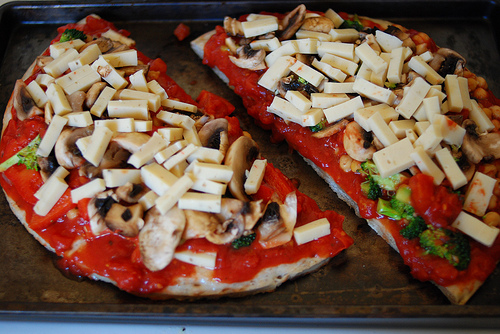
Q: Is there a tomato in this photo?
A: Yes, there is a tomato.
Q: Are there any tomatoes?
A: Yes, there is a tomato.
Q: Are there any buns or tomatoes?
A: Yes, there is a tomato.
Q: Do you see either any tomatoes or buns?
A: Yes, there is a tomato.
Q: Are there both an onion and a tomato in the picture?
A: No, there is a tomato but no onions.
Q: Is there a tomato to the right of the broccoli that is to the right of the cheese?
A: Yes, there is a tomato to the right of the broccoli.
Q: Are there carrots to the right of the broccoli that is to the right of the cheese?
A: No, there is a tomato to the right of the broccoli.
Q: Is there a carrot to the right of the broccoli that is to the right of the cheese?
A: No, there is a tomato to the right of the broccoli.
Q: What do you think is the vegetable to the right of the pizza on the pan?
A: The vegetable is a tomato.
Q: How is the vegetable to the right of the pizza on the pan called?
A: The vegetable is a tomato.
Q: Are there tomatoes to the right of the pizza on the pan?
A: Yes, there is a tomato to the right of the pizza.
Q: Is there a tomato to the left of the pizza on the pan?
A: No, the tomato is to the right of the pizza.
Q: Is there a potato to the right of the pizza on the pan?
A: No, there is a tomato to the right of the pizza.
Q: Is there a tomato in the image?
A: Yes, there is a tomato.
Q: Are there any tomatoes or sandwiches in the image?
A: Yes, there is a tomato.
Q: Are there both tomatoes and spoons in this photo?
A: No, there is a tomato but no spoons.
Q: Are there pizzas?
A: Yes, there is a pizza.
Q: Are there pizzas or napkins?
A: Yes, there is a pizza.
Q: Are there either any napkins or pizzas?
A: Yes, there is a pizza.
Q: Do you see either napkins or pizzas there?
A: Yes, there is a pizza.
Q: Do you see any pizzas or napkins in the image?
A: Yes, there is a pizza.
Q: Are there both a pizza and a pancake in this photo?
A: No, there is a pizza but no pancakes.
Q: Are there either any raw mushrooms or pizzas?
A: Yes, there is a raw pizza.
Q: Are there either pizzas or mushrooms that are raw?
A: Yes, the pizza is raw.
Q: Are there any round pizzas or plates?
A: Yes, there is a round pizza.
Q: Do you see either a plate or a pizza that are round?
A: Yes, the pizza is round.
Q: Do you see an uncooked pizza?
A: Yes, there is an uncooked pizza.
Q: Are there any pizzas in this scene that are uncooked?
A: Yes, there is a pizza that is uncooked.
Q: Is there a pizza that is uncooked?
A: Yes, there is a pizza that is uncooked.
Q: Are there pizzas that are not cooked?
A: Yes, there is a uncooked pizza.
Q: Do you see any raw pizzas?
A: Yes, there is a raw pizza.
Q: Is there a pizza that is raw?
A: Yes, there is a pizza that is raw.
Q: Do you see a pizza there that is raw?
A: Yes, there is a pizza that is raw.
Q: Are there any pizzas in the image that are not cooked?
A: Yes, there is a raw pizza.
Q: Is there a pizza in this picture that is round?
A: Yes, there is a round pizza.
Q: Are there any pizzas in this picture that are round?
A: Yes, there is a round pizza.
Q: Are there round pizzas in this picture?
A: Yes, there is a round pizza.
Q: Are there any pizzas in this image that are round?
A: Yes, there is a pizza that is round.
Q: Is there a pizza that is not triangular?
A: Yes, there is a round pizza.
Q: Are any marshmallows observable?
A: No, there are no marshmallows.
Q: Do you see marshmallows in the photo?
A: No, there are no marshmallows.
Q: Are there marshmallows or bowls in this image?
A: No, there are no marshmallows or bowls.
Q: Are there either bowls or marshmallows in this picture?
A: No, there are no marshmallows or bowls.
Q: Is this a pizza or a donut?
A: This is a pizza.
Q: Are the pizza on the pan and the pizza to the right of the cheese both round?
A: Yes, both the pizza and the pizza are round.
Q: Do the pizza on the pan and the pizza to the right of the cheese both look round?
A: Yes, both the pizza and the pizza are round.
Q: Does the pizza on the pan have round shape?
A: Yes, the pizza is round.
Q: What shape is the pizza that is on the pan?
A: The pizza is round.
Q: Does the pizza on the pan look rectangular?
A: No, the pizza is round.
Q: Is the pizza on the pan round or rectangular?
A: The pizza is round.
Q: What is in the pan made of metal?
A: The pizza is in the pan.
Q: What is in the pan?
A: The pizza is in the pan.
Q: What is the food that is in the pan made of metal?
A: The food is a pizza.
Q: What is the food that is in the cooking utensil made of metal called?
A: The food is a pizza.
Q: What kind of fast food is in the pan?
A: The food is a pizza.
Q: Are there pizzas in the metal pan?
A: Yes, there is a pizza in the pan.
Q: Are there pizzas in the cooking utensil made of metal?
A: Yes, there is a pizza in the pan.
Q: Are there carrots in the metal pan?
A: No, there is a pizza in the pan.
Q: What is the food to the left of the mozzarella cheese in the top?
A: The food is a pizza.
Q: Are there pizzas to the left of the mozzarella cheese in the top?
A: Yes, there is a pizza to the left of the mozzarella cheese.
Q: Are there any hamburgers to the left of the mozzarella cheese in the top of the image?
A: No, there is a pizza to the left of the mozzarella.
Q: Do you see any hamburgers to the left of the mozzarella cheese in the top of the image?
A: No, there is a pizza to the left of the mozzarella.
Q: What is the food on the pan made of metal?
A: The food is a pizza.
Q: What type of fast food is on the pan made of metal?
A: The food is a pizza.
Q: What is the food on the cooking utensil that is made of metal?
A: The food is a pizza.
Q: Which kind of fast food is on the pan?
A: The food is a pizza.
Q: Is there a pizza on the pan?
A: Yes, there is a pizza on the pan.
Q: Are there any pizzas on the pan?
A: Yes, there is a pizza on the pan.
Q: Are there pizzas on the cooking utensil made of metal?
A: Yes, there is a pizza on the pan.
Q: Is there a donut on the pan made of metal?
A: No, there is a pizza on the pan.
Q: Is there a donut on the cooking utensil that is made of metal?
A: No, there is a pizza on the pan.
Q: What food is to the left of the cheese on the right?
A: The food is a pizza.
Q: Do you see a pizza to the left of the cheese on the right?
A: Yes, there is a pizza to the left of the cheese.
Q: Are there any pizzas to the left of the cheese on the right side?
A: Yes, there is a pizza to the left of the cheese.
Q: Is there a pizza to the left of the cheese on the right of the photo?
A: Yes, there is a pizza to the left of the cheese.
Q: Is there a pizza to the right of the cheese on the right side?
A: No, the pizza is to the left of the cheese.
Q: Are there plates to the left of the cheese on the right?
A: No, there is a pizza to the left of the cheese.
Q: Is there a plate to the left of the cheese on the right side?
A: No, there is a pizza to the left of the cheese.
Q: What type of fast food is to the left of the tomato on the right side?
A: The food is a pizza.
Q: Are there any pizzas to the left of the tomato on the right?
A: Yes, there is a pizza to the left of the tomato.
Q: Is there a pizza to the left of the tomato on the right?
A: Yes, there is a pizza to the left of the tomato.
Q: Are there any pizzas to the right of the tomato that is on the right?
A: No, the pizza is to the left of the tomato.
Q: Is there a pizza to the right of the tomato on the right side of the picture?
A: No, the pizza is to the left of the tomato.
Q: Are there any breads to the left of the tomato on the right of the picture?
A: No, there is a pizza to the left of the tomato.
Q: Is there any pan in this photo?
A: Yes, there is a pan.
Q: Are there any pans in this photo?
A: Yes, there is a pan.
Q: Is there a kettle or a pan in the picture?
A: Yes, there is a pan.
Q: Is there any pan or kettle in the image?
A: Yes, there is a pan.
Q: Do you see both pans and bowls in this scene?
A: No, there is a pan but no bowls.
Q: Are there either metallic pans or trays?
A: Yes, there is a metal pan.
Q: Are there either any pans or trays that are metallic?
A: Yes, the pan is metallic.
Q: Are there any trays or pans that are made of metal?
A: Yes, the pan is made of metal.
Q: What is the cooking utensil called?
A: The cooking utensil is a pan.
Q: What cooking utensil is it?
A: The cooking utensil is a pan.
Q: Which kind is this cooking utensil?
A: This is a pan.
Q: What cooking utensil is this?
A: This is a pan.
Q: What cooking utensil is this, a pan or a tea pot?
A: This is a pan.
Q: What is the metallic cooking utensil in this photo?
A: The cooking utensil is a pan.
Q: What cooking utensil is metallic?
A: The cooking utensil is a pan.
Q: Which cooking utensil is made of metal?
A: The cooking utensil is a pan.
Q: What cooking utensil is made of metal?
A: The cooking utensil is a pan.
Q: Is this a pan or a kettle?
A: This is a pan.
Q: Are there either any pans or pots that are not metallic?
A: No, there is a pan but it is metallic.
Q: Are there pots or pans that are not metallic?
A: No, there is a pan but it is metallic.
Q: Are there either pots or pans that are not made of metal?
A: No, there is a pan but it is made of metal.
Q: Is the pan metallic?
A: Yes, the pan is metallic.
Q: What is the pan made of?
A: The pan is made of metal.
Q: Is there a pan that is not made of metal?
A: No, there is a pan but it is made of metal.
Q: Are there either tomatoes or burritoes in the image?
A: Yes, there is a tomato.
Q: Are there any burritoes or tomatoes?
A: Yes, there is a tomato.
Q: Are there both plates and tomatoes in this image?
A: No, there is a tomato but no plates.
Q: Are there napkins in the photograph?
A: No, there are no napkins.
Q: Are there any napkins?
A: No, there are no napkins.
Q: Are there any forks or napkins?
A: No, there are no napkins or forks.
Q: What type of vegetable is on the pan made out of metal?
A: The vegetable is a tomato.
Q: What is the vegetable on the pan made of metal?
A: The vegetable is a tomato.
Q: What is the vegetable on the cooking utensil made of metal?
A: The vegetable is a tomato.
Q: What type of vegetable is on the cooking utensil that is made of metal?
A: The vegetable is a tomato.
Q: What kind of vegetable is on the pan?
A: The vegetable is a tomato.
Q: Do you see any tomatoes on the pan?
A: Yes, there is a tomato on the pan.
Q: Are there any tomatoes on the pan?
A: Yes, there is a tomato on the pan.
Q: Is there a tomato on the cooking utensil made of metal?
A: Yes, there is a tomato on the pan.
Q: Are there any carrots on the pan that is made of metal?
A: No, there is a tomato on the pan.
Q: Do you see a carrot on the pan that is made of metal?
A: No, there is a tomato on the pan.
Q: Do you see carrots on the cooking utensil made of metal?
A: No, there is a tomato on the pan.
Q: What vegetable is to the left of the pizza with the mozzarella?
A: The vegetable is a tomato.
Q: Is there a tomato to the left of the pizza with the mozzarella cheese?
A: Yes, there is a tomato to the left of the pizza.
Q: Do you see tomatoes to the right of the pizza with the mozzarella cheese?
A: No, the tomato is to the left of the pizza.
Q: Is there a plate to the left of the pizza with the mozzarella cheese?
A: No, there is a tomato to the left of the pizza.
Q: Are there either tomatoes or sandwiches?
A: Yes, there is a tomato.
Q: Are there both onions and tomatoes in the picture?
A: No, there is a tomato but no onions.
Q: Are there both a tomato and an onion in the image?
A: No, there is a tomato but no onions.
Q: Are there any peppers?
A: No, there are no peppers.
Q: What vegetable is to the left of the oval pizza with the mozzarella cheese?
A: The vegetable is a tomato.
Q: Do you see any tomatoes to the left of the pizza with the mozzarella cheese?
A: Yes, there is a tomato to the left of the pizza.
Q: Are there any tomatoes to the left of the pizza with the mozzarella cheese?
A: Yes, there is a tomato to the left of the pizza.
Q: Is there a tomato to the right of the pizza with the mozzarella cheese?
A: No, the tomato is to the left of the pizza.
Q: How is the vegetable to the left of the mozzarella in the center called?
A: The vegetable is a tomato.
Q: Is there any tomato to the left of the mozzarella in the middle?
A: Yes, there is a tomato to the left of the mozzarella cheese.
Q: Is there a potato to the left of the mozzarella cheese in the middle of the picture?
A: No, there is a tomato to the left of the mozzarella cheese.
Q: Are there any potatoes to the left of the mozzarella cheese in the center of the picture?
A: No, there is a tomato to the left of the mozzarella cheese.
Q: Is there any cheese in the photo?
A: Yes, there is cheese.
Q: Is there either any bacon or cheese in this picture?
A: Yes, there is cheese.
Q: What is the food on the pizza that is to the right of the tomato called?
A: The food is cheese.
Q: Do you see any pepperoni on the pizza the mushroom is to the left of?
A: No, there is cheese on the pizza.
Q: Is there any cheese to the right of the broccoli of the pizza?
A: Yes, there is cheese to the right of the broccoli.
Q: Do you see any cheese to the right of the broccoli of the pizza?
A: Yes, there is cheese to the right of the broccoli.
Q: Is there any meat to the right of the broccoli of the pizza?
A: No, there is cheese to the right of the broccoli.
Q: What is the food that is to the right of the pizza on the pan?
A: The food is cheese.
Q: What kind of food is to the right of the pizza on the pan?
A: The food is cheese.